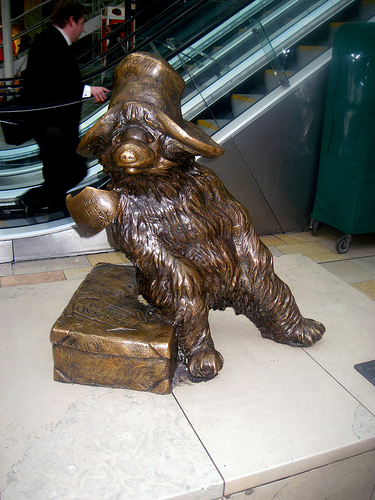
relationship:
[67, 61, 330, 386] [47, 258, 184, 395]
statue seated on a box